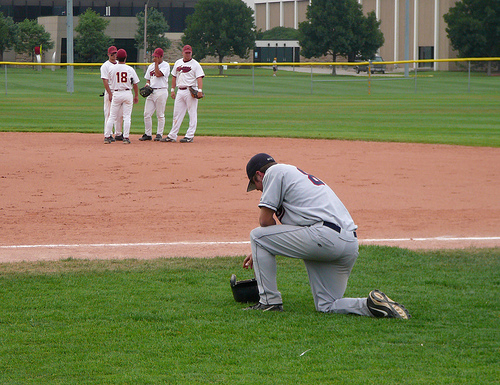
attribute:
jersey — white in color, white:
[170, 58, 203, 89]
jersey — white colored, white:
[148, 62, 168, 88]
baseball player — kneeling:
[241, 154, 417, 323]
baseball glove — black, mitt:
[229, 279, 263, 308]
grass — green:
[12, 246, 500, 384]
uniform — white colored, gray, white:
[252, 159, 357, 228]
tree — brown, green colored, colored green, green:
[296, 2, 385, 78]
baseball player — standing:
[96, 44, 140, 137]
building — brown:
[234, 3, 498, 74]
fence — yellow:
[2, 59, 500, 105]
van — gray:
[349, 52, 386, 75]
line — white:
[3, 236, 500, 249]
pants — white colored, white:
[251, 215, 376, 318]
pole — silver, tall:
[66, 0, 76, 91]